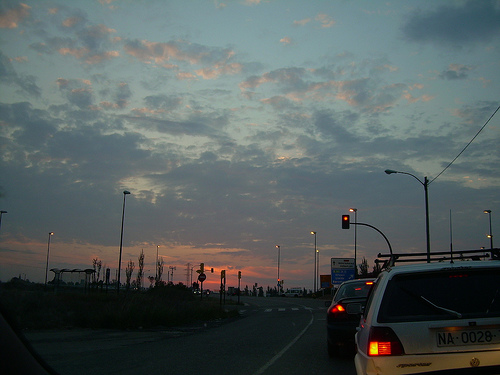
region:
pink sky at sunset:
[189, 254, 250, 268]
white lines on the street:
[266, 295, 313, 315]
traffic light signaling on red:
[334, 208, 360, 236]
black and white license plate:
[438, 325, 498, 347]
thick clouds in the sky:
[160, 37, 331, 117]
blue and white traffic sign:
[329, 254, 369, 281]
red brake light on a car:
[365, 320, 418, 365]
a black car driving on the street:
[329, 282, 364, 352]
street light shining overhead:
[34, 219, 64, 266]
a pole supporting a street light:
[420, 189, 439, 246]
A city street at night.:
[47, 166, 496, 365]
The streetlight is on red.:
[336, 208, 359, 241]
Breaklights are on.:
[308, 257, 485, 371]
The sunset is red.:
[156, 235, 306, 301]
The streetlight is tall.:
[107, 179, 138, 298]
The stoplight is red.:
[190, 264, 215, 300]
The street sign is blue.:
[322, 244, 363, 295]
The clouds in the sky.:
[32, 87, 462, 237]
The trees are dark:
[34, 249, 201, 299]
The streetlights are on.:
[264, 228, 331, 260]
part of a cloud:
[245, 145, 290, 197]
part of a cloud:
[231, 172, 278, 249]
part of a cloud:
[206, 191, 251, 231]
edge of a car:
[320, 307, 332, 344]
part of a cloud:
[203, 197, 241, 248]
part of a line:
[271, 323, 298, 358]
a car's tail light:
[326, 301, 343, 314]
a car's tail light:
[364, 326, 404, 353]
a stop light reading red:
[340, 213, 349, 227]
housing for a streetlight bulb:
[384, 168, 395, 175]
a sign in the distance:
[197, 273, 206, 283]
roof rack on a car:
[369, 247, 499, 265]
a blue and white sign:
[329, 257, 356, 286]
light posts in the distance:
[482, 208, 495, 254]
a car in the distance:
[192, 288, 199, 294]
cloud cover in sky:
[3, 2, 496, 282]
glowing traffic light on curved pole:
[340, 213, 392, 252]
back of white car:
[358, 257, 495, 373]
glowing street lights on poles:
[275, 205, 357, 290]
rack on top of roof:
[375, 245, 497, 275]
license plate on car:
[431, 323, 496, 349]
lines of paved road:
[240, 304, 322, 369]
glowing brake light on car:
[327, 278, 376, 353]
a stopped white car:
[353, 260, 498, 371]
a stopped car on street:
[323, 273, 385, 355]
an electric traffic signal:
[340, 212, 350, 230]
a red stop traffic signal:
[341, 213, 348, 220]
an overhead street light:
[382, 166, 424, 186]